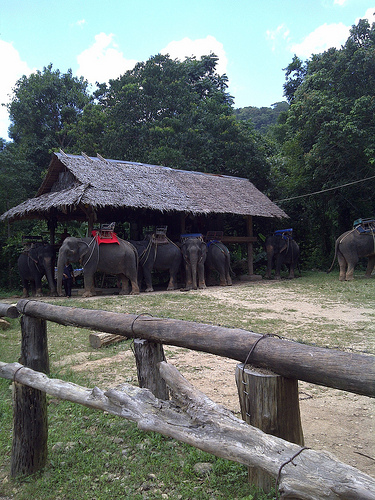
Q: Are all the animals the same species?
A: Yes, all the animals are elephants.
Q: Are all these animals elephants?
A: Yes, all the animals are elephants.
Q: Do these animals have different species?
A: No, all the animals are elephants.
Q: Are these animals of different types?
A: No, all the animals are elephants.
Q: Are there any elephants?
A: Yes, there is an elephant.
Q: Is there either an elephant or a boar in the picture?
A: Yes, there is an elephant.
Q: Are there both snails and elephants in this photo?
A: No, there is an elephant but no snails.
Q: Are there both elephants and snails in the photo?
A: No, there is an elephant but no snails.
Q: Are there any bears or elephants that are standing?
A: Yes, the elephant is standing.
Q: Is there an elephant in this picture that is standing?
A: Yes, there is an elephant that is standing.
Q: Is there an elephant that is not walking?
A: Yes, there is an elephant that is standing.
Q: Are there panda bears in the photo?
A: No, there are no panda bears.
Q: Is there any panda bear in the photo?
A: No, there are no panda bears.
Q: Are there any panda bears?
A: No, there are no panda bears.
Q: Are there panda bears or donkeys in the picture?
A: No, there are no panda bears or donkeys.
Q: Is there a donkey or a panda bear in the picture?
A: No, there are no panda bears or donkeys.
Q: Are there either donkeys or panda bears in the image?
A: No, there are no panda bears or donkeys.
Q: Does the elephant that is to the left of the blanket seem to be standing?
A: Yes, the elephant is standing.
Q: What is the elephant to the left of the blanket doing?
A: The elephant is standing.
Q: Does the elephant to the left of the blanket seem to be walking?
A: No, the elephant is standing.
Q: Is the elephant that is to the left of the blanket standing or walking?
A: The elephant is standing.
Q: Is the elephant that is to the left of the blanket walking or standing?
A: The elephant is standing.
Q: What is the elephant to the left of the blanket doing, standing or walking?
A: The elephant is standing.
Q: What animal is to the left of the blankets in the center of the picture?
A: The animal is an elephant.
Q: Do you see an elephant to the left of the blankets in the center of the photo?
A: Yes, there is an elephant to the left of the blankets.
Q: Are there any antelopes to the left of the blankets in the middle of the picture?
A: No, there is an elephant to the left of the blankets.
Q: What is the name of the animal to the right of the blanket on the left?
A: The animal is an elephant.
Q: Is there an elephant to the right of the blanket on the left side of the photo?
A: Yes, there is an elephant to the right of the blanket.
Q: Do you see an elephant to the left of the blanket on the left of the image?
A: No, the elephant is to the right of the blanket.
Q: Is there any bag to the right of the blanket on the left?
A: No, there is an elephant to the right of the blanket.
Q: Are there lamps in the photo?
A: No, there are no lamps.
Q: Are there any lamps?
A: No, there are no lamps.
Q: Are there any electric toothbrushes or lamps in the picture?
A: No, there are no lamps or electric toothbrushes.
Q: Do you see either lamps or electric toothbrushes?
A: No, there are no lamps or electric toothbrushes.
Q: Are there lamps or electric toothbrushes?
A: No, there are no lamps or electric toothbrushes.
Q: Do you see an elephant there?
A: Yes, there is an elephant.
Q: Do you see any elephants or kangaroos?
A: Yes, there is an elephant.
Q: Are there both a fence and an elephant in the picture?
A: Yes, there are both an elephant and a fence.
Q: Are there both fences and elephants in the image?
A: Yes, there are both an elephant and a fence.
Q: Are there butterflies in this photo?
A: No, there are no butterflies.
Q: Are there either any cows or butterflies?
A: No, there are no butterflies or cows.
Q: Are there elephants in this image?
A: Yes, there is an elephant.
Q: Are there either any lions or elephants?
A: Yes, there is an elephant.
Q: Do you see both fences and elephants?
A: Yes, there are both an elephant and a fence.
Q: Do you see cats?
A: No, there are no cats.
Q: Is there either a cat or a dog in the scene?
A: No, there are no cats or dogs.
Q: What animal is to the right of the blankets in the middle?
A: The animal is an elephant.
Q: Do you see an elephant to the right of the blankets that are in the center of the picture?
A: Yes, there is an elephant to the right of the blankets.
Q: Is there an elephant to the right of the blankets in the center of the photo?
A: Yes, there is an elephant to the right of the blankets.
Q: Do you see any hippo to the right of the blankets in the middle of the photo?
A: No, there is an elephant to the right of the blankets.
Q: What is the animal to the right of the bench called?
A: The animal is an elephant.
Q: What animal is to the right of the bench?
A: The animal is an elephant.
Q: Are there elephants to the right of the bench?
A: Yes, there is an elephant to the right of the bench.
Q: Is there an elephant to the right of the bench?
A: Yes, there is an elephant to the right of the bench.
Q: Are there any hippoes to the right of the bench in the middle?
A: No, there is an elephant to the right of the bench.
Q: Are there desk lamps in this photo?
A: No, there are no desk lamps.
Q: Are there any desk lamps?
A: No, there are no desk lamps.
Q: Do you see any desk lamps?
A: No, there are no desk lamps.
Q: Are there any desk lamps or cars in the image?
A: No, there are no desk lamps or cars.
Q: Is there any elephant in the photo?
A: Yes, there is an elephant.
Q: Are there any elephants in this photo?
A: Yes, there is an elephant.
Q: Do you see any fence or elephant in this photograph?
A: Yes, there is an elephant.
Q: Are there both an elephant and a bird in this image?
A: No, there is an elephant but no birds.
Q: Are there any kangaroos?
A: No, there are no kangaroos.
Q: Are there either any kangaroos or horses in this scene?
A: No, there are no kangaroos or horses.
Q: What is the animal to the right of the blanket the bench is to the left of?
A: The animal is an elephant.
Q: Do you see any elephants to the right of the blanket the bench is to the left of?
A: Yes, there is an elephant to the right of the blanket.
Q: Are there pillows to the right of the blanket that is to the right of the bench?
A: No, there is an elephant to the right of the blanket.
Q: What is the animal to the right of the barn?
A: The animal is an elephant.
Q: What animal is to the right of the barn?
A: The animal is an elephant.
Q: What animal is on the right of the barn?
A: The animal is an elephant.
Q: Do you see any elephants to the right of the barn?
A: Yes, there is an elephant to the right of the barn.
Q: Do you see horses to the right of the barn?
A: No, there is an elephant to the right of the barn.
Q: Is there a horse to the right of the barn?
A: No, there is an elephant to the right of the barn.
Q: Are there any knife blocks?
A: No, there are no knife blocks.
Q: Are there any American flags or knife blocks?
A: No, there are no knife blocks or American flags.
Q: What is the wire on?
A: The wire is on the post.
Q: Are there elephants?
A: Yes, there is an elephant.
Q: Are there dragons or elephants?
A: Yes, there is an elephant.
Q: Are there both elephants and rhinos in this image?
A: No, there is an elephant but no rhinos.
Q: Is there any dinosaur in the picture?
A: No, there are no dinosaurs.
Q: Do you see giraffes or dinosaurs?
A: No, there are no dinosaurs or giraffes.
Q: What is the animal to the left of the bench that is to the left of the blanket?
A: The animal is an elephant.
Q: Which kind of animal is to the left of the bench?
A: The animal is an elephant.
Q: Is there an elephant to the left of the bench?
A: Yes, there is an elephant to the left of the bench.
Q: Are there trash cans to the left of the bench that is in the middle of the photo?
A: No, there is an elephant to the left of the bench.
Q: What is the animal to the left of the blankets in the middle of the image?
A: The animal is an elephant.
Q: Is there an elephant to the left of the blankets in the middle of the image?
A: Yes, there is an elephant to the left of the blankets.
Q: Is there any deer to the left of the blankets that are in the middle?
A: No, there is an elephant to the left of the blankets.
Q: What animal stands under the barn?
A: The elephant stands under the barn.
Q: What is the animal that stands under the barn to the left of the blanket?
A: The animal is an elephant.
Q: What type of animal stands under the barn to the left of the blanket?
A: The animal is an elephant.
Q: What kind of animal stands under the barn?
A: The animal is an elephant.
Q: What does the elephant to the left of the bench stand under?
A: The elephant stands under the barn.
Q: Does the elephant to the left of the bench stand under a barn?
A: Yes, the elephant stands under a barn.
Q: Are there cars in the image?
A: No, there are no cars.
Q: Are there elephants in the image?
A: Yes, there is an elephant.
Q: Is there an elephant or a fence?
A: Yes, there is an elephant.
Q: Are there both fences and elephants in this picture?
A: Yes, there are both an elephant and a fence.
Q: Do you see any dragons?
A: No, there are no dragons.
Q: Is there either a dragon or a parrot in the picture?
A: No, there are no dragons or parrots.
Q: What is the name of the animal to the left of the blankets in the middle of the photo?
A: The animal is an elephant.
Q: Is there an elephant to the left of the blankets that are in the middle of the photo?
A: Yes, there is an elephant to the left of the blankets.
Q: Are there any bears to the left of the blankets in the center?
A: No, there is an elephant to the left of the blankets.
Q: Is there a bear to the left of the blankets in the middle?
A: No, there is an elephant to the left of the blankets.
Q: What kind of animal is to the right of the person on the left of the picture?
A: The animal is an elephant.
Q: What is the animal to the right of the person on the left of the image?
A: The animal is an elephant.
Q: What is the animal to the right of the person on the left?
A: The animal is an elephant.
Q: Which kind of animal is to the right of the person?
A: The animal is an elephant.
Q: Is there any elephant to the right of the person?
A: Yes, there is an elephant to the right of the person.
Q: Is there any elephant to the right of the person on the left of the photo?
A: Yes, there is an elephant to the right of the person.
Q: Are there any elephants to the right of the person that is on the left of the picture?
A: Yes, there is an elephant to the right of the person.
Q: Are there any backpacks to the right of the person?
A: No, there is an elephant to the right of the person.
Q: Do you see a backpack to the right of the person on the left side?
A: No, there is an elephant to the right of the person.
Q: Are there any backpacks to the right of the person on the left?
A: No, there is an elephant to the right of the person.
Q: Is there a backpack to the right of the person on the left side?
A: No, there is an elephant to the right of the person.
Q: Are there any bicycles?
A: No, there are no bicycles.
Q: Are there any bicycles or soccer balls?
A: No, there are no bicycles or soccer balls.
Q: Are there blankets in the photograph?
A: Yes, there is a blanket.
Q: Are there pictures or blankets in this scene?
A: Yes, there is a blanket.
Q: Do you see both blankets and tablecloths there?
A: No, there is a blanket but no tablecloths.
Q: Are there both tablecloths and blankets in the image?
A: No, there is a blanket but no tablecloths.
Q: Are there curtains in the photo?
A: No, there are no curtains.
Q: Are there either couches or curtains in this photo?
A: No, there are no curtains or couches.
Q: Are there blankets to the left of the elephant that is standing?
A: Yes, there is a blanket to the left of the elephant.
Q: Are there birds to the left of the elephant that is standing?
A: No, there is a blanket to the left of the elephant.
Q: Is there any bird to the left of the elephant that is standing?
A: No, there is a blanket to the left of the elephant.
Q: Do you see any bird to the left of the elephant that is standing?
A: No, there is a blanket to the left of the elephant.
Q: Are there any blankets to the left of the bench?
A: Yes, there is a blanket to the left of the bench.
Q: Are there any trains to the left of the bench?
A: No, there is a blanket to the left of the bench.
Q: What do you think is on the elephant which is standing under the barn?
A: The blanket is on the elephant.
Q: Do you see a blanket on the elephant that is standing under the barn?
A: Yes, there is a blanket on the elephant.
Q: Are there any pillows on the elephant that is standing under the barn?
A: No, there is a blanket on the elephant.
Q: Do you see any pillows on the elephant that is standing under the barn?
A: No, there is a blanket on the elephant.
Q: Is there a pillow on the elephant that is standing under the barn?
A: No, there is a blanket on the elephant.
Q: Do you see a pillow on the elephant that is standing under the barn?
A: No, there is a blanket on the elephant.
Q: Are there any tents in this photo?
A: No, there are no tents.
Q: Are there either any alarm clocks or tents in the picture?
A: No, there are no tents or alarm clocks.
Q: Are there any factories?
A: No, there are no factories.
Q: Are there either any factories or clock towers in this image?
A: No, there are no factories or clock towers.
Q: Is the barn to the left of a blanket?
A: Yes, the barn is to the left of a blanket.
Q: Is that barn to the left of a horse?
A: No, the barn is to the left of a blanket.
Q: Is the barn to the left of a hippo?
A: No, the barn is to the left of the elephant.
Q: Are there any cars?
A: No, there are no cars.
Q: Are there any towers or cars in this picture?
A: No, there are no cars or towers.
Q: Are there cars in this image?
A: No, there are no cars.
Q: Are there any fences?
A: Yes, there is a fence.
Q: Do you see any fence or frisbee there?
A: Yes, there is a fence.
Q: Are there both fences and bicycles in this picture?
A: No, there is a fence but no bicycles.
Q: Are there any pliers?
A: No, there are no pliers.